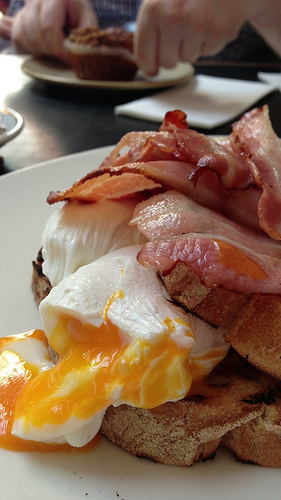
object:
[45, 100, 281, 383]
bacon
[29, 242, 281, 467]
bread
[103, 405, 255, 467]
crust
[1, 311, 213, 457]
yolk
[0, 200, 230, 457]
egg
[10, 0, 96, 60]
hand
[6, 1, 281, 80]
person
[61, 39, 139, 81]
wrapper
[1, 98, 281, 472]
sandwich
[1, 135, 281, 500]
plate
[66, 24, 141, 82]
muffin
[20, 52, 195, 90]
plate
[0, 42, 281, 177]
table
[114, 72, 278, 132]
napkin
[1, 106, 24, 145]
edge of bowl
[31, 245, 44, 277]
burnt edge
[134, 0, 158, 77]
finger